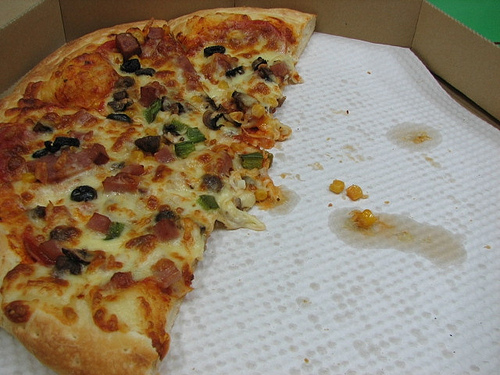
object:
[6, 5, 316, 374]
pizza half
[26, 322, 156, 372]
crust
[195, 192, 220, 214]
green pepper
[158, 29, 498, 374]
paper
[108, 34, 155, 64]
ham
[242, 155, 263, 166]
diced greenpepper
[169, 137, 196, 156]
diced greenpepper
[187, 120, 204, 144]
diced greenpepper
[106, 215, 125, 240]
diced greenpepper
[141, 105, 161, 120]
diced greenpepper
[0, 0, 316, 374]
pizza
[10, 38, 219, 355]
pizza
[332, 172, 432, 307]
grease stains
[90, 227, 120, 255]
cheese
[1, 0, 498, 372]
box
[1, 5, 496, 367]
photograph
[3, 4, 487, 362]
cardboard container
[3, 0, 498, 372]
packaging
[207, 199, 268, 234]
cheese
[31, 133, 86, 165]
olives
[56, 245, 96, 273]
mushroom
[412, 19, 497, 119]
box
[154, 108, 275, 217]
peppers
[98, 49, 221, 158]
kernals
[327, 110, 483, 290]
pizza